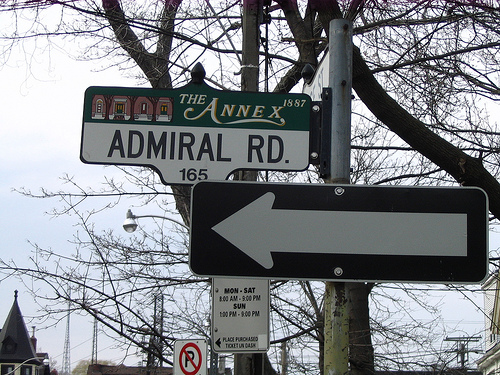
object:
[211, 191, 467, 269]
arrow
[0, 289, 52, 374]
building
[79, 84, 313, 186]
street sign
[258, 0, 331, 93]
trees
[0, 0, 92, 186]
clouds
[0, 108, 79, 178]
skies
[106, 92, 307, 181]
text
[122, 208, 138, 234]
lamp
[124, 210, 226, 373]
street light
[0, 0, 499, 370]
branches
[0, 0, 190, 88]
tree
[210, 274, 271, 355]
sign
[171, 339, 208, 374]
no parking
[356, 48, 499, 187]
trunk of a tree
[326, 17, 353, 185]
gray metal pole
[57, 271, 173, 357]
telephone cables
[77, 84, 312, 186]
road signage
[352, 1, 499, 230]
trees in the photo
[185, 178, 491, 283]
black sign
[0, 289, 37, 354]
black roof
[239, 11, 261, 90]
metal pole with sign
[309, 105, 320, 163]
metal bolt of sign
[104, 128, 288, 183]
admiral rd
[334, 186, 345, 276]
street sign bolted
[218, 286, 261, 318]
hours listed on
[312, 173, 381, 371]
pole holding up